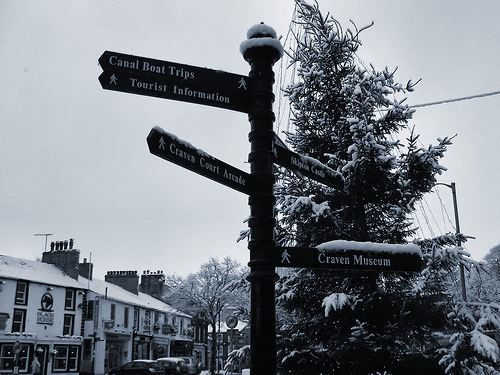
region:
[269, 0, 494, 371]
fir tree covered in snow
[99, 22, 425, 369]
street sign on the corner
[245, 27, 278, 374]
black snow-covered pole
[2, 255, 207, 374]
white buildings in the distance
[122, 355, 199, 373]
cars parked in front of the buildings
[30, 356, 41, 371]
person walking down the street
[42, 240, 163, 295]
chimneys on the roof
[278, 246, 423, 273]
sign pointing toward the museum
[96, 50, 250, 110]
sign pointing toward boat trips and tourist info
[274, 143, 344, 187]
sign pointing toward the castle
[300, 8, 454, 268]
tall tree covered with snow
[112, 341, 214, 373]
Cars parked in front of building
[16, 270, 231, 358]
Building across the road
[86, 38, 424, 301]
signboard showing different direction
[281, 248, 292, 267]
Drawing of a man to show walking direction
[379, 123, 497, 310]
Electric pole and wires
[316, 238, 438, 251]
snow resting on the top of ba signboard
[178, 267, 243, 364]
Tree growing in frond of a house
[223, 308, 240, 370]
Circular one stand signboard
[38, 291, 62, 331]
Name and logo of the bulding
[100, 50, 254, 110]
black and white street sign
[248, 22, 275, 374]
black iron sign pole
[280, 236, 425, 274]
sign covered in snow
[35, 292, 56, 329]
black sign on building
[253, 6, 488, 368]
tree covered in snow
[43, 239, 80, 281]
brick chimney on building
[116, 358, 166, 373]
car parked on street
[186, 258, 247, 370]
tree with no leaves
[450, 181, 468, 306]
brown wooden street lamp pole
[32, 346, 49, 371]
black door in building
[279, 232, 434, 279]
Snow on the bottom sign.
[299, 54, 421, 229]
Snow is on the trees.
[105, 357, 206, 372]
Cars parked in front of the building.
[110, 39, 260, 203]
Signs on the pole.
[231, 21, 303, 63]
The top of the pole has snow.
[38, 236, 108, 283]
Chimneys on top of the building.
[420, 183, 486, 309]
A lightpole near the tree.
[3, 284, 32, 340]
The building has windows.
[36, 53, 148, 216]
The sky is clear.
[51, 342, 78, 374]
The door to the building.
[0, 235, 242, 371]
This is a house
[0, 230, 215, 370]
This is a building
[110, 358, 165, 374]
This is a car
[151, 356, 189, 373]
This is a car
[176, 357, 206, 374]
This is a car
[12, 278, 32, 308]
This is a window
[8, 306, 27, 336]
This is a window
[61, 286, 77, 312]
This is a window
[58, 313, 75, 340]
This is a window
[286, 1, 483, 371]
This is a tree